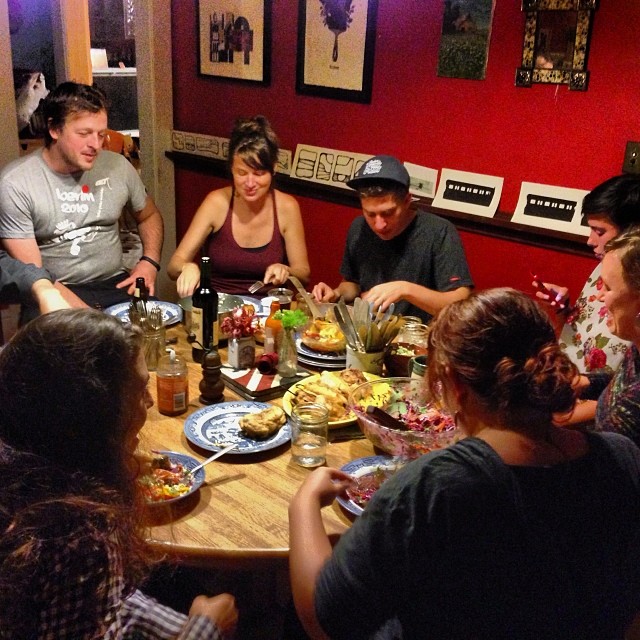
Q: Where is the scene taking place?
A: In a dining room.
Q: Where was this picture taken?
A: In a home.